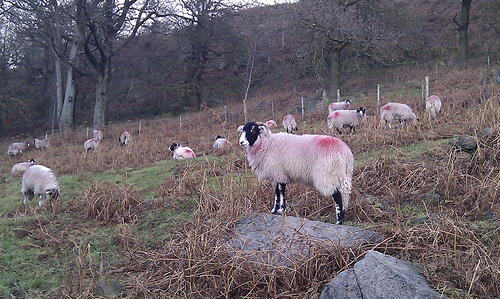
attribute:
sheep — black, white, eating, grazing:
[6, 94, 440, 227]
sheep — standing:
[237, 121, 354, 224]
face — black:
[237, 122, 258, 147]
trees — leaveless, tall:
[1, 1, 499, 129]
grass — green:
[120, 171, 161, 188]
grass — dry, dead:
[192, 255, 246, 294]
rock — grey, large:
[214, 212, 382, 279]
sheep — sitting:
[168, 134, 234, 166]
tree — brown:
[33, 0, 191, 140]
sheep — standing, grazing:
[20, 165, 60, 215]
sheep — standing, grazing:
[378, 101, 421, 131]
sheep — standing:
[424, 95, 441, 117]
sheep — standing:
[119, 131, 132, 146]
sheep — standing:
[83, 137, 103, 155]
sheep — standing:
[9, 140, 32, 159]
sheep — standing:
[327, 98, 350, 115]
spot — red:
[332, 113, 338, 119]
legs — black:
[330, 190, 346, 228]